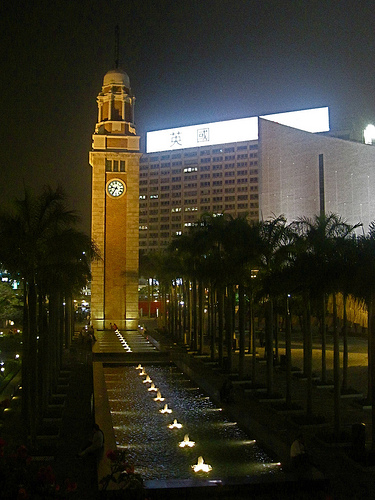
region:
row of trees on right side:
[165, 211, 374, 450]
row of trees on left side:
[6, 186, 96, 471]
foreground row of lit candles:
[127, 361, 214, 479]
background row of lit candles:
[113, 322, 131, 352]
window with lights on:
[137, 160, 221, 247]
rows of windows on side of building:
[141, 153, 248, 261]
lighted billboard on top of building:
[142, 109, 330, 149]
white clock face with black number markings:
[105, 178, 122, 196]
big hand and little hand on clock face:
[107, 183, 119, 195]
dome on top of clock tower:
[101, 71, 130, 87]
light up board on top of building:
[143, 107, 332, 153]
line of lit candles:
[98, 314, 211, 473]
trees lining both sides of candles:
[11, 187, 355, 398]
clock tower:
[91, 53, 143, 325]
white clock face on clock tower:
[102, 174, 125, 199]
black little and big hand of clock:
[111, 185, 119, 194]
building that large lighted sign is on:
[127, 134, 262, 290]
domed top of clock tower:
[91, 66, 135, 89]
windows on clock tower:
[105, 158, 126, 170]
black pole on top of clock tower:
[108, 23, 124, 65]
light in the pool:
[105, 350, 258, 497]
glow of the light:
[234, 438, 249, 448]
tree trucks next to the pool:
[182, 299, 352, 421]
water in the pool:
[81, 349, 289, 492]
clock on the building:
[99, 177, 129, 201]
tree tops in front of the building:
[155, 207, 355, 308]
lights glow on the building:
[88, 311, 137, 329]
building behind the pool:
[127, 98, 372, 296]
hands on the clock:
[108, 183, 119, 195]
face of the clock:
[106, 179, 126, 198]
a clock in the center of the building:
[101, 175, 127, 198]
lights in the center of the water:
[107, 323, 209, 475]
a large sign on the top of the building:
[137, 107, 341, 139]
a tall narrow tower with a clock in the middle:
[85, 66, 142, 336]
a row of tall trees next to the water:
[150, 217, 374, 391]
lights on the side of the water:
[239, 435, 279, 469]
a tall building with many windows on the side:
[141, 124, 374, 241]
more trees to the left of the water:
[9, 191, 84, 404]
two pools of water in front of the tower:
[92, 321, 284, 491]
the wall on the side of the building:
[253, 121, 374, 234]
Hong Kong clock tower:
[90, 58, 143, 332]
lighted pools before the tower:
[96, 321, 273, 498]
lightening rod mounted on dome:
[98, 9, 134, 88]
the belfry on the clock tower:
[94, 89, 141, 140]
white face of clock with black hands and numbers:
[104, 176, 128, 199]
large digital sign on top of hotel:
[143, 105, 335, 164]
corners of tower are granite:
[83, 152, 108, 333]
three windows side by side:
[100, 155, 129, 176]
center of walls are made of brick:
[107, 142, 126, 320]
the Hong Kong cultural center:
[255, 109, 374, 278]